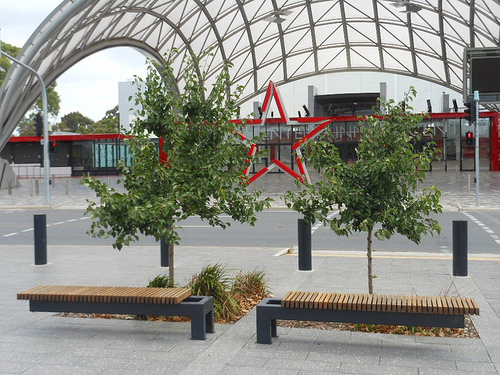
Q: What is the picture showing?
A: It is showing a street.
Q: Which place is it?
A: It is a street.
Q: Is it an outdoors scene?
A: Yes, it is outdoors.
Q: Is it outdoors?
A: Yes, it is outdoors.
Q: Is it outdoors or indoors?
A: It is outdoors.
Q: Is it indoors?
A: No, it is outdoors.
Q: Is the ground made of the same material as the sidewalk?
A: Yes, both the ground and the sidewalk are made of concrete.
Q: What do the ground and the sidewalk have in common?
A: The material, both the ground and the sidewalk are concrete.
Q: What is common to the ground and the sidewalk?
A: The material, both the ground and the sidewalk are concrete.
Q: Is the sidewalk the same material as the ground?
A: Yes, both the sidewalk and the ground are made of concrete.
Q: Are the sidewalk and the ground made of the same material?
A: Yes, both the sidewalk and the ground are made of concrete.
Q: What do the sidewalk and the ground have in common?
A: The material, both the sidewalk and the ground are concrete.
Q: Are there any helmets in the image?
A: No, there are no helmets.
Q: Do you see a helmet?
A: No, there are no helmets.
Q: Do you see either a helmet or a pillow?
A: No, there are no helmets or pillows.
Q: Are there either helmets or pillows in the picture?
A: No, there are no helmets or pillows.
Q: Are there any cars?
A: No, there are no cars.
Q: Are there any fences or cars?
A: No, there are no cars or fences.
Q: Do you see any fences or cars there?
A: No, there are no cars or fences.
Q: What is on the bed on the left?
A: The tree is on the bed.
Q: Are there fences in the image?
A: No, there are no fences.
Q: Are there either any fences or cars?
A: No, there are no fences or cars.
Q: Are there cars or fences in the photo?
A: No, there are no fences or cars.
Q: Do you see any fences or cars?
A: No, there are no fences or cars.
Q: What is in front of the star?
A: The tree is in front of the star.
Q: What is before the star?
A: The tree is in front of the star.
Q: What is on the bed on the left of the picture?
A: The tree is on the bed.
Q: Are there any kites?
A: No, there are no kites.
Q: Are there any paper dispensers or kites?
A: No, there are no kites or paper dispensers.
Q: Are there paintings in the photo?
A: No, there are no paintings.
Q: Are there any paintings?
A: No, there are no paintings.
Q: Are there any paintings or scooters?
A: No, there are no paintings or scooters.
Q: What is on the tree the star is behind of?
A: The leaves are on the tree.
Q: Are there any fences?
A: No, there are no fences.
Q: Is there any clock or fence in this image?
A: No, there are no fences or clocks.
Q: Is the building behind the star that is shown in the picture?
A: Yes, the building is behind the star.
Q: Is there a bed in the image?
A: Yes, there is a bed.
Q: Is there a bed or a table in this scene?
A: Yes, there is a bed.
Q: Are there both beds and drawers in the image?
A: No, there is a bed but no drawers.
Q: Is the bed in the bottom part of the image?
A: Yes, the bed is in the bottom of the image.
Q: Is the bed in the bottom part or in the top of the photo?
A: The bed is in the bottom of the image.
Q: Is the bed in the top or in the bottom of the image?
A: The bed is in the bottom of the image.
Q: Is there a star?
A: Yes, there is a star.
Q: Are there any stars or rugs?
A: Yes, there is a star.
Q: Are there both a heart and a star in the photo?
A: No, there is a star but no hearts.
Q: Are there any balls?
A: No, there are no balls.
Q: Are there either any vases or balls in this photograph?
A: No, there are no balls or vases.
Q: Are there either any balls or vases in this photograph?
A: No, there are no balls or vases.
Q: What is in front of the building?
A: The star is in front of the building.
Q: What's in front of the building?
A: The star is in front of the building.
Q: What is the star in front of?
A: The star is in front of the building.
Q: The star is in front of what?
A: The star is in front of the building.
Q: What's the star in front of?
A: The star is in front of the building.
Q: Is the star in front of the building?
A: Yes, the star is in front of the building.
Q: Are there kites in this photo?
A: No, there are no kites.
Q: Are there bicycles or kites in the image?
A: No, there are no kites or bicycles.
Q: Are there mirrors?
A: No, there are no mirrors.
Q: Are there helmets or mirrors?
A: No, there are no mirrors or helmets.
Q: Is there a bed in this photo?
A: Yes, there is a bed.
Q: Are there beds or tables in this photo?
A: Yes, there is a bed.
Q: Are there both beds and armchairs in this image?
A: No, there is a bed but no armchairs.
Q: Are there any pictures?
A: No, there are no pictures.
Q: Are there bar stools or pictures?
A: No, there are no pictures or bar stools.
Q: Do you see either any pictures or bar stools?
A: No, there are no pictures or bar stools.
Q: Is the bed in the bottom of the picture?
A: Yes, the bed is in the bottom of the image.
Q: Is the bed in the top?
A: No, the bed is in the bottom of the image.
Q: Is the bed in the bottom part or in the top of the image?
A: The bed is in the bottom of the image.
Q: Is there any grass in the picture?
A: Yes, there is grass.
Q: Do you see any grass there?
A: Yes, there is grass.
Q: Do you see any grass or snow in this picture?
A: Yes, there is grass.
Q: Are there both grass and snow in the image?
A: No, there is grass but no snow.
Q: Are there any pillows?
A: No, there are no pillows.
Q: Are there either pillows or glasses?
A: No, there are no pillows or glasses.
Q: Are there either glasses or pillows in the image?
A: No, there are no pillows or glasses.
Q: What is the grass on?
A: The grass is on the bed.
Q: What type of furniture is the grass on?
A: The grass is on the bed.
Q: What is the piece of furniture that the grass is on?
A: The piece of furniture is a bed.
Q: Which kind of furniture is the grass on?
A: The grass is on the bed.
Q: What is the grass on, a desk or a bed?
A: The grass is on a bed.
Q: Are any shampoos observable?
A: No, there are no shampoos.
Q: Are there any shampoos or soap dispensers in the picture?
A: No, there are no shampoos or soap dispensers.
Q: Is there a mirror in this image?
A: No, there are no mirrors.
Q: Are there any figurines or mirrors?
A: No, there are no mirrors or figurines.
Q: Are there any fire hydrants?
A: No, there are no fire hydrants.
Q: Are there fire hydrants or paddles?
A: No, there are no fire hydrants or paddles.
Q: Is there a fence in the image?
A: No, there are no fences.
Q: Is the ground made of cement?
A: Yes, the ground is made of cement.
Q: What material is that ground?
A: The ground is made of cement.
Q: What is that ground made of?
A: The ground is made of cement.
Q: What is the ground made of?
A: The ground is made of concrete.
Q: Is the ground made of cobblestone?
A: No, the ground is made of cement.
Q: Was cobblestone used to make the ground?
A: No, the ground is made of cement.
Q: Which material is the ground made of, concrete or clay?
A: The ground is made of concrete.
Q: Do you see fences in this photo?
A: No, there are no fences.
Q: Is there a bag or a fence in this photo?
A: No, there are no fences or bags.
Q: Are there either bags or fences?
A: No, there are no fences or bags.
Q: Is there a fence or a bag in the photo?
A: No, there are no fences or bags.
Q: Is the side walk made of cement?
A: Yes, the side walk is made of cement.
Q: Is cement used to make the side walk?
A: Yes, the side walk is made of cement.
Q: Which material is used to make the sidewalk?
A: The sidewalk is made of concrete.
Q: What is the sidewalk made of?
A: The sidewalk is made of concrete.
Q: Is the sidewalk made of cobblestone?
A: No, the sidewalk is made of cement.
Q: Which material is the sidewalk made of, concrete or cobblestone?
A: The sidewalk is made of concrete.